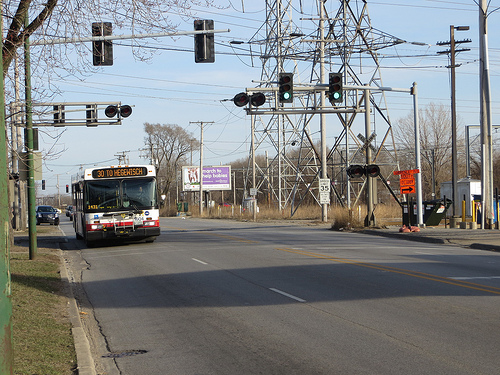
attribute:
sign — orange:
[390, 166, 431, 197]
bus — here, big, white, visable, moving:
[70, 163, 181, 247]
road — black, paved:
[177, 219, 334, 346]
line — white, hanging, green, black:
[259, 281, 311, 318]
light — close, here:
[272, 65, 303, 114]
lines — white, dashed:
[263, 282, 317, 312]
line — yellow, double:
[359, 250, 438, 299]